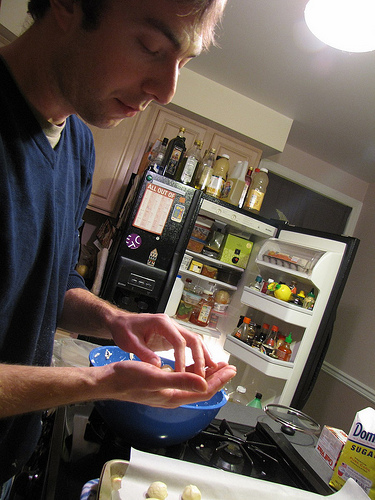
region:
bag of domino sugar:
[327, 404, 374, 492]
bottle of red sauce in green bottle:
[276, 327, 295, 363]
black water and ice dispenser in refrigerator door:
[113, 263, 157, 312]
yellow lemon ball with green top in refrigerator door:
[272, 281, 291, 299]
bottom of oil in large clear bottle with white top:
[220, 157, 250, 208]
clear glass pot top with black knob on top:
[262, 400, 322, 437]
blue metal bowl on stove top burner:
[82, 337, 231, 443]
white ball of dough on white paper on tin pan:
[142, 479, 170, 498]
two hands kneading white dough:
[103, 309, 239, 410]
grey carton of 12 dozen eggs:
[260, 244, 313, 273]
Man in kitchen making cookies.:
[2, 6, 248, 473]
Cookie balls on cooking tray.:
[92, 447, 348, 498]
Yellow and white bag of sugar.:
[325, 401, 374, 497]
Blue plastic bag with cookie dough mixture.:
[79, 342, 238, 445]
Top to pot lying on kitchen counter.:
[259, 395, 323, 445]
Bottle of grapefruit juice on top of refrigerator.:
[204, 147, 234, 201]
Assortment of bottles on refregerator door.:
[227, 313, 300, 364]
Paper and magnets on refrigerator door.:
[113, 161, 188, 273]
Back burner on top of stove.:
[199, 415, 284, 482]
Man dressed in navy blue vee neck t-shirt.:
[2, 86, 98, 484]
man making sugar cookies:
[1, 1, 237, 499]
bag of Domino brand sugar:
[325, 407, 374, 492]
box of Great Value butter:
[315, 424, 346, 470]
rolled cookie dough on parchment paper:
[144, 479, 206, 498]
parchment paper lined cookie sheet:
[92, 457, 365, 498]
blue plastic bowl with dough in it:
[84, 339, 226, 439]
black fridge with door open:
[94, 166, 357, 437]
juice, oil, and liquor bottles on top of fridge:
[138, 120, 269, 212]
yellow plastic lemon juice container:
[271, 281, 292, 301]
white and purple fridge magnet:
[123, 230, 143, 252]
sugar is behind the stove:
[324, 397, 370, 496]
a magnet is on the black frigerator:
[140, 241, 158, 264]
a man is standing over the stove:
[0, 0, 256, 495]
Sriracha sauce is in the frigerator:
[270, 325, 291, 356]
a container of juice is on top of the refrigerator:
[201, 143, 231, 195]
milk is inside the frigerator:
[161, 270, 182, 317]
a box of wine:
[214, 225, 259, 270]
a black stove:
[7, 383, 340, 498]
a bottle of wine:
[236, 159, 258, 208]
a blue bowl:
[87, 336, 233, 447]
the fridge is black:
[147, 186, 332, 352]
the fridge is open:
[143, 173, 332, 395]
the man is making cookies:
[79, 300, 264, 499]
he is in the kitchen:
[11, 69, 351, 499]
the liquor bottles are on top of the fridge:
[134, 124, 283, 212]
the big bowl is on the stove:
[82, 326, 230, 442]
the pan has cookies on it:
[91, 449, 219, 499]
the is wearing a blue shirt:
[8, 61, 160, 448]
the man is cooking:
[11, 63, 317, 498]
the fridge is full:
[142, 173, 309, 427]